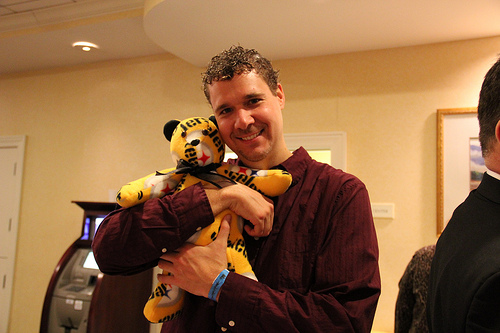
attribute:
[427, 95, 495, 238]
picture — wood framed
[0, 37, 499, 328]
wall — yellow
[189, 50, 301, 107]
hair — brown, curly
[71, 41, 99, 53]
lighting — recessed, round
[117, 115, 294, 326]
stuffed animal — yellow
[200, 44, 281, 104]
hair — curly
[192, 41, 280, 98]
hair — curly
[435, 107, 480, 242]
picture frame — wooden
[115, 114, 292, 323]
animal — stuffed, yellow, black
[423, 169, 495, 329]
jacket — black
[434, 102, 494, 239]
frame — brown, wooden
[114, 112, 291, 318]
bear — stuffed, yellow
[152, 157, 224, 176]
lace bow — brown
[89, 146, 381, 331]
shirt — burgundy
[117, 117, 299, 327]
bear — black, yellow, teddy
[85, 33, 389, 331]
man — long sleeved, black, wavy, smiling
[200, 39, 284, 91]
curly hair — brown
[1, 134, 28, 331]
door — white